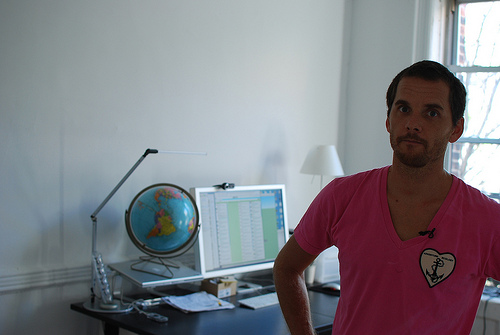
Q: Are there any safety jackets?
A: No, there are no safety jackets.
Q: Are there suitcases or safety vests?
A: No, there are no safety vests or suitcases.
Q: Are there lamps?
A: Yes, there is a lamp.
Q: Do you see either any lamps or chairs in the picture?
A: Yes, there is a lamp.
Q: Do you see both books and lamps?
A: No, there is a lamp but no books.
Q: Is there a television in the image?
A: No, there are no televisions.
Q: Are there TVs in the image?
A: No, there are no tvs.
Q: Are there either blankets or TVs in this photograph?
A: No, there are no TVs or blankets.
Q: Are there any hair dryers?
A: No, there are no hair dryers.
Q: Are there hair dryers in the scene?
A: No, there are no hair dryers.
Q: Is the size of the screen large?
A: Yes, the screen is large.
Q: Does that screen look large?
A: Yes, the screen is large.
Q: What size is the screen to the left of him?
A: The screen is large.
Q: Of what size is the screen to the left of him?
A: The screen is large.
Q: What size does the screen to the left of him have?
A: The screen has large size.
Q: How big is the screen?
A: The screen is large.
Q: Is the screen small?
A: No, the screen is large.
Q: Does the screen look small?
A: No, the screen is large.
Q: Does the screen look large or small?
A: The screen is large.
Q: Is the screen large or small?
A: The screen is large.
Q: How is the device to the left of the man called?
A: The device is a screen.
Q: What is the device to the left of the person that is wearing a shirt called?
A: The device is a screen.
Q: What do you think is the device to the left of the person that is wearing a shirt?
A: The device is a screen.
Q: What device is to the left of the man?
A: The device is a screen.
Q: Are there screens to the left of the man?
A: Yes, there is a screen to the left of the man.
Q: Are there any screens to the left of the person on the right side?
A: Yes, there is a screen to the left of the man.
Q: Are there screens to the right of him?
A: No, the screen is to the left of the man.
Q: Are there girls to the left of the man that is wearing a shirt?
A: No, there is a screen to the left of the man.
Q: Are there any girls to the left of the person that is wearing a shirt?
A: No, there is a screen to the left of the man.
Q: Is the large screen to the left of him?
A: Yes, the screen is to the left of a man.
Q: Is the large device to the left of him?
A: Yes, the screen is to the left of a man.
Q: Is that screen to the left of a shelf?
A: No, the screen is to the left of a man.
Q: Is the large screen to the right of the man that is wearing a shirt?
A: No, the screen is to the left of the man.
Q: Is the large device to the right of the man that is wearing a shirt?
A: No, the screen is to the left of the man.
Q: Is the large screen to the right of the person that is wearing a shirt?
A: No, the screen is to the left of the man.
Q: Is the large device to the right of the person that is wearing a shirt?
A: No, the screen is to the left of the man.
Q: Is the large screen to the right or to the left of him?
A: The screen is to the left of the man.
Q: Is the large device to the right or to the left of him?
A: The screen is to the left of the man.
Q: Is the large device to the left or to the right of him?
A: The screen is to the left of the man.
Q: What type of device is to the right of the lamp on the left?
A: The device is a screen.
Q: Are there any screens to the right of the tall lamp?
A: Yes, there is a screen to the right of the lamp.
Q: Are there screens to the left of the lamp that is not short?
A: No, the screen is to the right of the lamp.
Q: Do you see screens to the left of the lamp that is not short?
A: No, the screen is to the right of the lamp.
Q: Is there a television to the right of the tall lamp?
A: No, there is a screen to the right of the lamp.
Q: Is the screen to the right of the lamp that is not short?
A: Yes, the screen is to the right of the lamp.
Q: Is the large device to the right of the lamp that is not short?
A: Yes, the screen is to the right of the lamp.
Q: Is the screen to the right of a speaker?
A: No, the screen is to the right of the lamp.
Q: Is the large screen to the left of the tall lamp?
A: No, the screen is to the right of the lamp.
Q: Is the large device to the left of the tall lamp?
A: No, the screen is to the right of the lamp.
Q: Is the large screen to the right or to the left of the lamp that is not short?
A: The screen is to the right of the lamp.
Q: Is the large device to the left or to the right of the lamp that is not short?
A: The screen is to the right of the lamp.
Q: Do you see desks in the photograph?
A: Yes, there is a desk.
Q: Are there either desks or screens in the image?
A: Yes, there is a desk.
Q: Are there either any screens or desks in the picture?
A: Yes, there is a desk.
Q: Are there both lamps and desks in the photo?
A: Yes, there are both a desk and a lamp.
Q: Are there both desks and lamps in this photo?
A: Yes, there are both a desk and a lamp.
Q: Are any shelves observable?
A: No, there are no shelves.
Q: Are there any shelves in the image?
A: No, there are no shelves.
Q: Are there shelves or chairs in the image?
A: No, there are no shelves or chairs.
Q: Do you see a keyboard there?
A: Yes, there is a keyboard.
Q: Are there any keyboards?
A: Yes, there is a keyboard.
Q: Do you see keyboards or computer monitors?
A: Yes, there is a keyboard.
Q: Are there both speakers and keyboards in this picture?
A: No, there is a keyboard but no speakers.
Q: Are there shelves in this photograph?
A: No, there are no shelves.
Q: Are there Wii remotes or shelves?
A: No, there are no shelves or Wii remotes.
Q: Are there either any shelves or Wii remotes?
A: No, there are no shelves or Wii remotes.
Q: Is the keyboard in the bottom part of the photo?
A: Yes, the keyboard is in the bottom of the image.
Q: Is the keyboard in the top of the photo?
A: No, the keyboard is in the bottom of the image.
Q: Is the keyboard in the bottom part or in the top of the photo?
A: The keyboard is in the bottom of the image.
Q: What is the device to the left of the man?
A: The device is a keyboard.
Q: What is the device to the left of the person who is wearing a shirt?
A: The device is a keyboard.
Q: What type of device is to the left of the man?
A: The device is a keyboard.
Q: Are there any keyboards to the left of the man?
A: Yes, there is a keyboard to the left of the man.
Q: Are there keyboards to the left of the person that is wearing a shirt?
A: Yes, there is a keyboard to the left of the man.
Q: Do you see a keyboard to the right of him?
A: No, the keyboard is to the left of the man.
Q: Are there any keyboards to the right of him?
A: No, the keyboard is to the left of the man.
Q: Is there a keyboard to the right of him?
A: No, the keyboard is to the left of the man.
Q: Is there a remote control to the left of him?
A: No, there is a keyboard to the left of the man.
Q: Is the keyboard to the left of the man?
A: Yes, the keyboard is to the left of the man.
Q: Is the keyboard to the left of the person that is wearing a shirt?
A: Yes, the keyboard is to the left of the man.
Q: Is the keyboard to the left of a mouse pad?
A: No, the keyboard is to the left of the man.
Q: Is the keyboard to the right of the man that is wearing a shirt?
A: No, the keyboard is to the left of the man.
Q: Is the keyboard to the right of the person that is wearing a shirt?
A: No, the keyboard is to the left of the man.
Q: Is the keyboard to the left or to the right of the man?
A: The keyboard is to the left of the man.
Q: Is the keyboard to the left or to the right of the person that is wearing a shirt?
A: The keyboard is to the left of the man.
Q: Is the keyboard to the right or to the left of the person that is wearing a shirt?
A: The keyboard is to the left of the man.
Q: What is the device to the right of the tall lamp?
A: The device is a keyboard.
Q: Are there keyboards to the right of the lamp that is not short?
A: Yes, there is a keyboard to the right of the lamp.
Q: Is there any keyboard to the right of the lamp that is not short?
A: Yes, there is a keyboard to the right of the lamp.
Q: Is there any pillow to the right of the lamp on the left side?
A: No, there is a keyboard to the right of the lamp.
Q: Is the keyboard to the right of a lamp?
A: Yes, the keyboard is to the right of a lamp.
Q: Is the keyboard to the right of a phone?
A: No, the keyboard is to the right of a lamp.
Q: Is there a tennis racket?
A: No, there are no rackets.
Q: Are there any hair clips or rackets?
A: No, there are no rackets or hair clips.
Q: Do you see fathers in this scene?
A: No, there are no fathers.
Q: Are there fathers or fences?
A: No, there are no fathers or fences.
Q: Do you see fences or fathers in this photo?
A: No, there are no fathers or fences.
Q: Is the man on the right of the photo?
A: Yes, the man is on the right of the image.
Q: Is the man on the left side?
A: No, the man is on the right of the image.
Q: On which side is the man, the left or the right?
A: The man is on the right of the image.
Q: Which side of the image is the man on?
A: The man is on the right of the image.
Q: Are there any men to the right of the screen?
A: Yes, there is a man to the right of the screen.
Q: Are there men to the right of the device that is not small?
A: Yes, there is a man to the right of the screen.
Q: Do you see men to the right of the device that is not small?
A: Yes, there is a man to the right of the screen.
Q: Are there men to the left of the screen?
A: No, the man is to the right of the screen.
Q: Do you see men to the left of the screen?
A: No, the man is to the right of the screen.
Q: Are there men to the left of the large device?
A: No, the man is to the right of the screen.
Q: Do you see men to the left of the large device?
A: No, the man is to the right of the screen.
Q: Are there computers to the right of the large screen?
A: No, there is a man to the right of the screen.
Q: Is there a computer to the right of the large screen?
A: No, there is a man to the right of the screen.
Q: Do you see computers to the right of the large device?
A: No, there is a man to the right of the screen.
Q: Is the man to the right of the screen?
A: Yes, the man is to the right of the screen.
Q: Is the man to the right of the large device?
A: Yes, the man is to the right of the screen.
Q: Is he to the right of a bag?
A: No, the man is to the right of the screen.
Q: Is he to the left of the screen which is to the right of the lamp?
A: No, the man is to the right of the screen.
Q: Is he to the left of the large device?
A: No, the man is to the right of the screen.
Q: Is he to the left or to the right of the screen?
A: The man is to the right of the screen.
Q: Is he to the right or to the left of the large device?
A: The man is to the right of the screen.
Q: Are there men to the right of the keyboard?
A: Yes, there is a man to the right of the keyboard.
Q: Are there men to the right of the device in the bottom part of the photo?
A: Yes, there is a man to the right of the keyboard.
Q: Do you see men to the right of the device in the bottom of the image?
A: Yes, there is a man to the right of the keyboard.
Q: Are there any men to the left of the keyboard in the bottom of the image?
A: No, the man is to the right of the keyboard.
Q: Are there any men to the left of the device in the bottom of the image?
A: No, the man is to the right of the keyboard.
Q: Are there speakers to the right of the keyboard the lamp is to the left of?
A: No, there is a man to the right of the keyboard.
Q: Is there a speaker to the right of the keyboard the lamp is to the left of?
A: No, there is a man to the right of the keyboard.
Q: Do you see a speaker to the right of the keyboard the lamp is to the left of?
A: No, there is a man to the right of the keyboard.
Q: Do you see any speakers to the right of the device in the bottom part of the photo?
A: No, there is a man to the right of the keyboard.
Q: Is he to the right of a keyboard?
A: Yes, the man is to the right of a keyboard.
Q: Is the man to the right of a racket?
A: No, the man is to the right of a keyboard.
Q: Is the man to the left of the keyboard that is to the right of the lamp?
A: No, the man is to the right of the keyboard.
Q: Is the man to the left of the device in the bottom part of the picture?
A: No, the man is to the right of the keyboard.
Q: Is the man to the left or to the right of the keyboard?
A: The man is to the right of the keyboard.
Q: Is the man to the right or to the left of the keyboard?
A: The man is to the right of the keyboard.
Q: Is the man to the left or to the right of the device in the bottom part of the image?
A: The man is to the right of the keyboard.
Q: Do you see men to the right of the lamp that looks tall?
A: Yes, there is a man to the right of the lamp.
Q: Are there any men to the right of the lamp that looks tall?
A: Yes, there is a man to the right of the lamp.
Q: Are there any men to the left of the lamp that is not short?
A: No, the man is to the right of the lamp.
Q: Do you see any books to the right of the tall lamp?
A: No, there is a man to the right of the lamp.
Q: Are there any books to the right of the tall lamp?
A: No, there is a man to the right of the lamp.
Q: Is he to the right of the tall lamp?
A: Yes, the man is to the right of the lamp.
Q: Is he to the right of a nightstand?
A: No, the man is to the right of the lamp.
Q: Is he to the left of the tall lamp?
A: No, the man is to the right of the lamp.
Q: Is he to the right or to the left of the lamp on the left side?
A: The man is to the right of the lamp.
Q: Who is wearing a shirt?
A: The man is wearing a shirt.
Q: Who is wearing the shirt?
A: The man is wearing a shirt.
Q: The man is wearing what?
A: The man is wearing a shirt.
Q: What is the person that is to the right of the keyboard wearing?
A: The man is wearing a shirt.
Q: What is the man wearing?
A: The man is wearing a shirt.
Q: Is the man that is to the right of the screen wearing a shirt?
A: Yes, the man is wearing a shirt.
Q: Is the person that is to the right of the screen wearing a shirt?
A: Yes, the man is wearing a shirt.